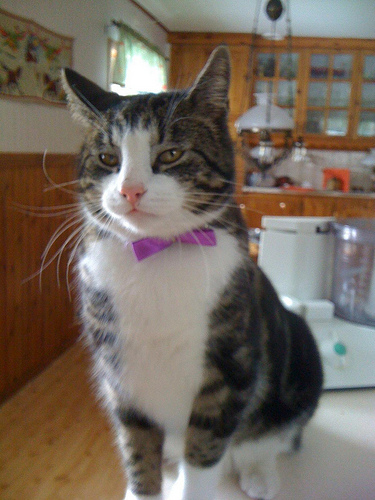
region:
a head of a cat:
[49, 42, 252, 269]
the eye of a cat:
[153, 143, 188, 168]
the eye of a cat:
[93, 145, 126, 172]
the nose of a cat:
[111, 174, 151, 204]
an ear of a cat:
[188, 44, 236, 116]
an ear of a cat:
[49, 61, 116, 138]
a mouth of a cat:
[109, 203, 162, 224]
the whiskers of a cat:
[24, 147, 109, 303]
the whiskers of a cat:
[173, 180, 272, 286]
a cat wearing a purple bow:
[44, 49, 262, 293]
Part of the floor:
[21, 417, 68, 458]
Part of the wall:
[8, 116, 38, 142]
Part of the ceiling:
[304, 10, 332, 19]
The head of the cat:
[52, 43, 241, 242]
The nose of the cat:
[117, 176, 148, 206]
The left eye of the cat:
[153, 144, 189, 168]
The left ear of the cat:
[185, 44, 236, 117]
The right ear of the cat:
[92, 147, 121, 169]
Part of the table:
[338, 419, 355, 459]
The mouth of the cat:
[121, 205, 161, 222]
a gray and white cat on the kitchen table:
[61, 45, 326, 498]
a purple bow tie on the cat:
[130, 232, 214, 262]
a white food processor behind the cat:
[260, 218, 374, 390]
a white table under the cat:
[165, 312, 369, 495]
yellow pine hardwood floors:
[1, 344, 128, 498]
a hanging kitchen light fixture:
[237, 1, 294, 163]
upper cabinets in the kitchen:
[253, 41, 373, 148]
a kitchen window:
[110, 31, 167, 93]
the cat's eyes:
[98, 150, 180, 169]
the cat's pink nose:
[122, 186, 142, 205]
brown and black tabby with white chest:
[17, 39, 322, 499]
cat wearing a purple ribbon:
[14, 41, 325, 497]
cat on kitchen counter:
[16, 41, 373, 498]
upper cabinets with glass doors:
[245, 35, 373, 149]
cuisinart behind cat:
[11, 41, 373, 495]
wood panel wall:
[2, 0, 173, 409]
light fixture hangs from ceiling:
[131, 0, 374, 165]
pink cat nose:
[120, 181, 147, 205]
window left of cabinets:
[103, 29, 373, 146]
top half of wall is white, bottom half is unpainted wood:
[2, 5, 174, 404]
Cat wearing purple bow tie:
[15, 44, 324, 498]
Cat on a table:
[23, 42, 327, 498]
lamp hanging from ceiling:
[229, 0, 301, 184]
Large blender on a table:
[256, 211, 373, 418]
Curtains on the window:
[101, 16, 170, 95]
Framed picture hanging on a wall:
[0, 2, 78, 109]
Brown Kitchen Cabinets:
[162, 29, 373, 229]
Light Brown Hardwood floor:
[0, 325, 125, 496]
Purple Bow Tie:
[128, 225, 219, 265]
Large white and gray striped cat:
[26, 41, 320, 497]